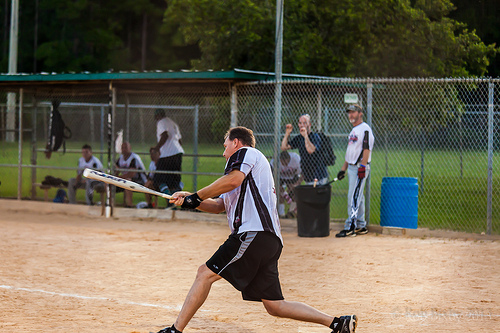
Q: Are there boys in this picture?
A: No, there are no boys.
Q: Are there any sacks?
A: No, there are no sacks.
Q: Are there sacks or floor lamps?
A: No, there are no sacks or floor lamps.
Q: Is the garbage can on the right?
A: Yes, the garbage can is on the right of the image.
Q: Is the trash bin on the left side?
A: No, the trash bin is on the right of the image.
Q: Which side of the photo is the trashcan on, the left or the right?
A: The trashcan is on the right of the image.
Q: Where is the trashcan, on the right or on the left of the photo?
A: The trashcan is on the right of the image.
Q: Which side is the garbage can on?
A: The garbage can is on the right of the image.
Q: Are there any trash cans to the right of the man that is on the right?
A: Yes, there is a trash can to the right of the man.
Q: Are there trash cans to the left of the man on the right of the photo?
A: No, the trash can is to the right of the man.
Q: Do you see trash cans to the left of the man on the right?
A: No, the trash can is to the right of the man.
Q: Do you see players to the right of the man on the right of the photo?
A: No, there is a trash can to the right of the man.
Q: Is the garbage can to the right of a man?
A: Yes, the garbage can is to the right of a man.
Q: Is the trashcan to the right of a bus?
A: No, the trashcan is to the right of a man.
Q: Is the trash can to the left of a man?
A: No, the trash can is to the right of a man.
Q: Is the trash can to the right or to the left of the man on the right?
A: The trash can is to the right of the man.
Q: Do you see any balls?
A: No, there are no balls.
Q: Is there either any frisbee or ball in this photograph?
A: No, there are no balls or frisbees.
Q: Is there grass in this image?
A: Yes, there is grass.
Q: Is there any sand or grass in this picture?
A: Yes, there is grass.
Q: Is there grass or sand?
A: Yes, there is grass.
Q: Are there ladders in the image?
A: No, there are no ladders.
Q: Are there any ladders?
A: No, there are no ladders.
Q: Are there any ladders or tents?
A: No, there are no ladders or tents.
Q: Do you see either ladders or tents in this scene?
A: No, there are no ladders or tents.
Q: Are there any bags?
A: Yes, there is a bag.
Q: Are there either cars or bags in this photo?
A: Yes, there is a bag.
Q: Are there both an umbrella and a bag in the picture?
A: No, there is a bag but no umbrellas.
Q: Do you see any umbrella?
A: No, there are no umbrellas.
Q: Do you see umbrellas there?
A: No, there are no umbrellas.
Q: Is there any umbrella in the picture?
A: No, there are no umbrellas.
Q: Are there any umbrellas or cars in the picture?
A: No, there are no umbrellas or cars.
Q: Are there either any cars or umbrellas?
A: No, there are no umbrellas or cars.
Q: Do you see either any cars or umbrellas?
A: No, there are no umbrellas or cars.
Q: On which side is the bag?
A: The bag is on the left of the image.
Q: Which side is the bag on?
A: The bag is on the left of the image.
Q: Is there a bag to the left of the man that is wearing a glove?
A: Yes, there is a bag to the left of the man.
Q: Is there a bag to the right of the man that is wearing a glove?
A: No, the bag is to the left of the man.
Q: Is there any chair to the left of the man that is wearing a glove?
A: No, there is a bag to the left of the man.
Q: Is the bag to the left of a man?
A: Yes, the bag is to the left of a man.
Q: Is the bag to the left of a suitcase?
A: No, the bag is to the left of a man.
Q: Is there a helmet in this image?
A: No, there are no helmets.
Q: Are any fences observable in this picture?
A: Yes, there is a fence.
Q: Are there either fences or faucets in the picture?
A: Yes, there is a fence.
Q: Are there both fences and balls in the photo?
A: No, there is a fence but no balls.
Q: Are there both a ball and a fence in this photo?
A: No, there is a fence but no balls.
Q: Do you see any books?
A: No, there are no books.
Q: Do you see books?
A: No, there are no books.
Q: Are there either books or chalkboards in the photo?
A: No, there are no books or chalkboards.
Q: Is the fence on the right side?
A: Yes, the fence is on the right of the image.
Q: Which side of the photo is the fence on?
A: The fence is on the right of the image.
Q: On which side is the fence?
A: The fence is on the right of the image.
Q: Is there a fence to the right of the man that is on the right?
A: Yes, there is a fence to the right of the man.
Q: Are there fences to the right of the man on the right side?
A: Yes, there is a fence to the right of the man.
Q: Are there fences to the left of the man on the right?
A: No, the fence is to the right of the man.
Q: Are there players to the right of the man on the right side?
A: No, there is a fence to the right of the man.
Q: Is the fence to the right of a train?
A: No, the fence is to the right of the man.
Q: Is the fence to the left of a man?
A: No, the fence is to the right of a man.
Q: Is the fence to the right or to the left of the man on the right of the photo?
A: The fence is to the right of the man.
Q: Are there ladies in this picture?
A: No, there are no ladies.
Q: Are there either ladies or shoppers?
A: No, there are no ladies or shoppers.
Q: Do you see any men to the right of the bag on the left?
A: Yes, there is a man to the right of the bag.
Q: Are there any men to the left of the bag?
A: No, the man is to the right of the bag.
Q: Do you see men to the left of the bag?
A: No, the man is to the right of the bag.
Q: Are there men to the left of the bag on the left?
A: No, the man is to the right of the bag.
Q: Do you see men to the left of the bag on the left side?
A: No, the man is to the right of the bag.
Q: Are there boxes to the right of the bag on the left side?
A: No, there is a man to the right of the bag.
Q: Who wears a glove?
A: The man wears a glove.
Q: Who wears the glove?
A: The man wears a glove.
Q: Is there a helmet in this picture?
A: No, there are no helmets.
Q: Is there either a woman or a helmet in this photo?
A: No, there are no helmets or women.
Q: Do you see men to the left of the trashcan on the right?
A: Yes, there is a man to the left of the garbage can.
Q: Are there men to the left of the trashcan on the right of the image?
A: Yes, there is a man to the left of the garbage can.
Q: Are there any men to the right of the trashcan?
A: No, the man is to the left of the trashcan.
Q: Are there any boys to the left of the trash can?
A: No, there is a man to the left of the trash can.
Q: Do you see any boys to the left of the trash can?
A: No, there is a man to the left of the trash can.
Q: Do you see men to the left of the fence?
A: Yes, there is a man to the left of the fence.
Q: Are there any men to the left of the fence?
A: Yes, there is a man to the left of the fence.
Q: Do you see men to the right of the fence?
A: No, the man is to the left of the fence.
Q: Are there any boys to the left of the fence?
A: No, there is a man to the left of the fence.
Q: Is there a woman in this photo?
A: No, there are no women.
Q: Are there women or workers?
A: No, there are no women or workers.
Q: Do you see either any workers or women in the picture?
A: No, there are no women or workers.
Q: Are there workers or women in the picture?
A: No, there are no women or workers.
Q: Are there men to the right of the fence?
A: No, the man is to the left of the fence.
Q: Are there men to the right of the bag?
A: Yes, there is a man to the right of the bag.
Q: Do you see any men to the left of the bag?
A: No, the man is to the right of the bag.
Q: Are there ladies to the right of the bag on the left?
A: No, there is a man to the right of the bag.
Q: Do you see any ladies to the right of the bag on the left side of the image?
A: No, there is a man to the right of the bag.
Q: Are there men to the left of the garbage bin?
A: Yes, there is a man to the left of the garbage bin.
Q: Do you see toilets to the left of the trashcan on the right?
A: No, there is a man to the left of the trashcan.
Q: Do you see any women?
A: No, there are no women.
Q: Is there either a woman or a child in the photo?
A: No, there are no women or children.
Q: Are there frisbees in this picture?
A: No, there are no frisbees.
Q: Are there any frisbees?
A: No, there are no frisbees.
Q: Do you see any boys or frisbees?
A: No, there are no frisbees or boys.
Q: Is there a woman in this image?
A: No, there are no women.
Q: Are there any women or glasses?
A: No, there are no women or glasses.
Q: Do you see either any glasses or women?
A: No, there are no women or glasses.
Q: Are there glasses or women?
A: No, there are no women or glasses.